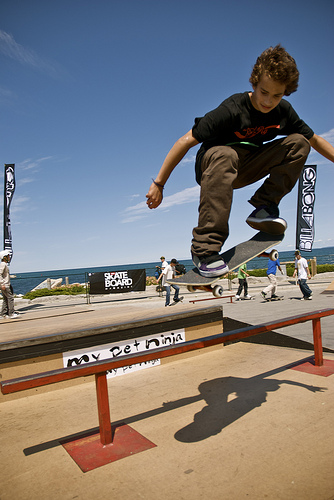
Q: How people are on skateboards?
A: Five.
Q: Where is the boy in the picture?
A: In the air.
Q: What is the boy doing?
A: Skateboarding.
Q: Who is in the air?
A: A boy.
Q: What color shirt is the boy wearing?
A: Black.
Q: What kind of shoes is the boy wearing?
A: Sneakers.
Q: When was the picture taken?
A: During the day.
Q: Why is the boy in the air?
A: He jumped.